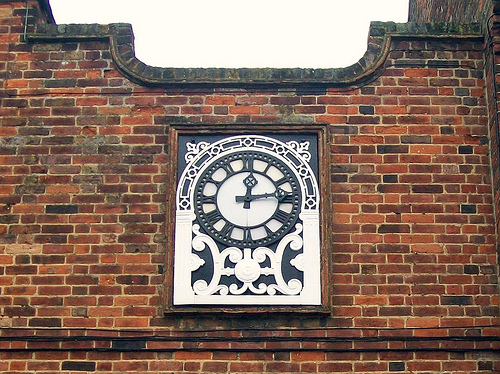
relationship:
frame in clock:
[183, 137, 311, 305] [197, 154, 289, 241]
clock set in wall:
[161, 120, 335, 317] [3, 4, 498, 371]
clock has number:
[191, 151, 302, 249] [241, 156, 247, 166]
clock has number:
[191, 151, 302, 249] [263, 161, 272, 173]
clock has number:
[191, 151, 302, 249] [273, 175, 288, 185]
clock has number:
[191, 151, 302, 249] [273, 208, 288, 223]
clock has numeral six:
[191, 151, 302, 249] [243, 227, 254, 242]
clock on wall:
[191, 151, 302, 249] [3, 4, 498, 371]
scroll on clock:
[191, 223, 304, 294] [175, 131, 320, 304]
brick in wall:
[333, 295, 496, 326] [3, 4, 498, 371]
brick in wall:
[324, 349, 499, 371] [3, 4, 498, 371]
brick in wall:
[0, 351, 230, 371] [3, 4, 498, 371]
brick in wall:
[0, 280, 162, 325] [3, 4, 498, 371]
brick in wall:
[331, 124, 482, 246] [3, 4, 498, 371]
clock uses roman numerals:
[191, 151, 302, 249] [262, 160, 293, 221]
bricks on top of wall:
[328, 84, 479, 93] [3, 4, 498, 371]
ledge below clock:
[2, 315, 500, 360] [191, 151, 302, 249]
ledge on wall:
[2, 315, 500, 360] [3, 4, 498, 371]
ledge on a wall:
[2, 315, 474, 360] [18, 297, 449, 372]